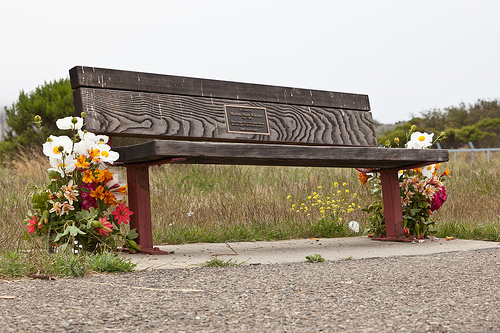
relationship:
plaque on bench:
[224, 103, 271, 137] [68, 63, 449, 255]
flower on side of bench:
[24, 113, 132, 244] [68, 63, 449, 255]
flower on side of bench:
[110, 198, 138, 227] [68, 63, 449, 255]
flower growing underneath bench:
[288, 181, 362, 218] [68, 63, 449, 255]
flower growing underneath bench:
[340, 181, 349, 188] [68, 63, 449, 255]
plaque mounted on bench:
[224, 104, 269, 134] [68, 63, 449, 255]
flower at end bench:
[24, 113, 132, 244] [68, 63, 449, 255]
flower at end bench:
[288, 181, 362, 218] [68, 63, 449, 255]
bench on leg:
[68, 63, 449, 255] [371, 170, 413, 240]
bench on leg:
[68, 63, 449, 255] [124, 162, 168, 256]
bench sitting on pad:
[68, 63, 449, 255] [116, 233, 496, 271]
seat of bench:
[112, 139, 446, 166] [68, 63, 449, 255]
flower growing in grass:
[288, 181, 362, 218] [2, 150, 499, 277]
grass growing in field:
[2, 150, 499, 277] [2, 149, 496, 277]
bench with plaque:
[68, 63, 449, 255] [224, 103, 271, 137]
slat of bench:
[72, 86, 374, 143] [68, 63, 449, 255]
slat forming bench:
[71, 65, 446, 162] [68, 63, 449, 255]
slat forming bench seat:
[71, 65, 446, 162] [109, 137, 451, 175]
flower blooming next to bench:
[24, 113, 132, 244] [68, 63, 449, 255]